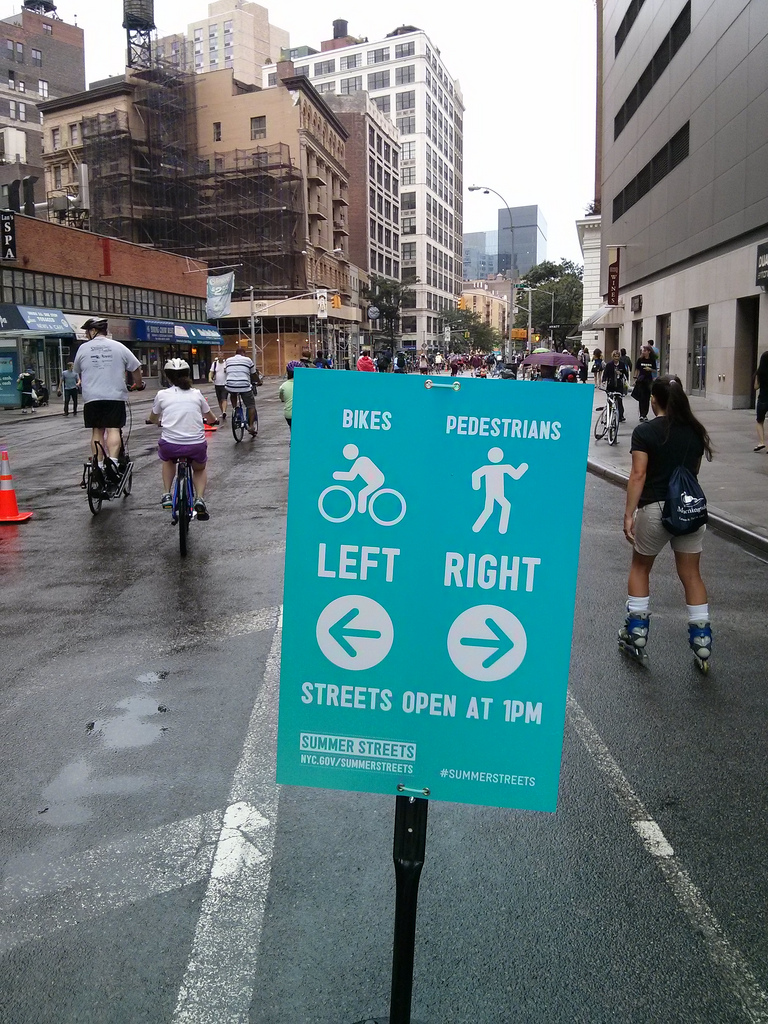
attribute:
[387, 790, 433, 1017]
pole — black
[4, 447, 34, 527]
cane — Orange and white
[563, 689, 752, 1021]
line — white 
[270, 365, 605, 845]
sign — white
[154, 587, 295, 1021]
line — white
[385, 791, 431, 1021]
pole — black